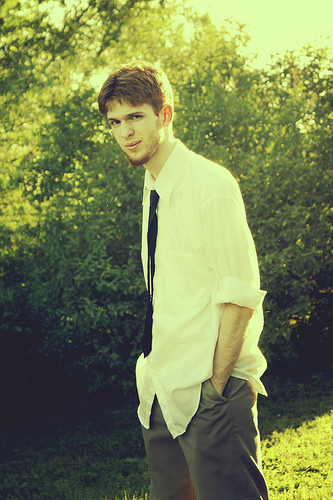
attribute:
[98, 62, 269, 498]
guy — handsome, tall, redhead, standing, walking, young, smiling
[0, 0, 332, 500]
garden — green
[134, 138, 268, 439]
t-shirt — white, untucked, long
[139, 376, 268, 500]
pants — grey, gray, brown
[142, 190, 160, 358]
tie — black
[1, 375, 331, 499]
grass — green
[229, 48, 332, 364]
bush — big, green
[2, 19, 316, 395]
bush — big, green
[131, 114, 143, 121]
eye — black, small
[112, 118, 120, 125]
eye — black, small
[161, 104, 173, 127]
ear — small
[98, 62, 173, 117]
hair — orange, short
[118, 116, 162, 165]
beard — orange, short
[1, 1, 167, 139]
leaves — green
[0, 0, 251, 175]
leaves — green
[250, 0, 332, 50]
sun — shining, bright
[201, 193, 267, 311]
sleeve — long